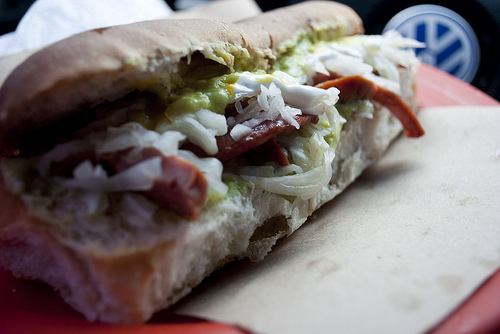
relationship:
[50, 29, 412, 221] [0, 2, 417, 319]
veggies on sandwich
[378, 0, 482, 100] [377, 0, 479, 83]
logo on wheel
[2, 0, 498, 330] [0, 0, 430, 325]
napkin under food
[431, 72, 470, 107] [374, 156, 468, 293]
plate under napkin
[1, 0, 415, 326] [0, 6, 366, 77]
bread has top part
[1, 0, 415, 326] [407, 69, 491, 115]
bread on plate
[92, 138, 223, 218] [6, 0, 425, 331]
meat on bun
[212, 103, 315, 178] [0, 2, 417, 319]
meat topping sandwich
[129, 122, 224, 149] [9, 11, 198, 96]
cheese on bread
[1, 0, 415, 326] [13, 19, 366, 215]
bread on a bun